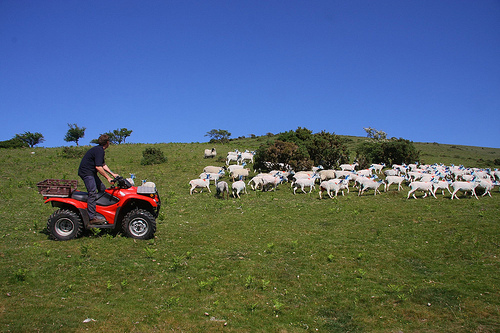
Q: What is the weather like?
A: It is clear.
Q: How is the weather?
A: It is clear.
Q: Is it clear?
A: Yes, it is clear.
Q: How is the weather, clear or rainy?
A: It is clear.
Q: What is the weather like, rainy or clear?
A: It is clear.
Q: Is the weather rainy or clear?
A: It is clear.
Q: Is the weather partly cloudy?
A: No, it is clear.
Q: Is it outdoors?
A: Yes, it is outdoors.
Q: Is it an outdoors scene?
A: Yes, it is outdoors.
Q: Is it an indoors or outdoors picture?
A: It is outdoors.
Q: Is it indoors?
A: No, it is outdoors.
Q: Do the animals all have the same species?
A: Yes, all the animals are sheep.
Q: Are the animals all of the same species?
A: Yes, all the animals are sheep.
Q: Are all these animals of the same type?
A: Yes, all the animals are sheep.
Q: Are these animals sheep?
A: Yes, all the animals are sheep.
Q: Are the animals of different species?
A: No, all the animals are sheep.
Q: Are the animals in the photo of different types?
A: No, all the animals are sheep.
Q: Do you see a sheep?
A: Yes, there is a sheep.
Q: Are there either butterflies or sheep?
A: Yes, there is a sheep.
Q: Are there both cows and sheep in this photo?
A: No, there is a sheep but no cows.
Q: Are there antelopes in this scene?
A: No, there are no antelopes.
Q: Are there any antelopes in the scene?
A: No, there are no antelopes.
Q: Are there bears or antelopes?
A: No, there are no antelopes or bears.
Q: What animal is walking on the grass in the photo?
A: The sheep is walking on the grass.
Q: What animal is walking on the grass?
A: The sheep is walking on the grass.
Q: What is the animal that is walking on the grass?
A: The animal is a sheep.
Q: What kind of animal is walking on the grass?
A: The animal is a sheep.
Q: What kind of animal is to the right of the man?
A: The animal is a sheep.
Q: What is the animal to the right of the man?
A: The animal is a sheep.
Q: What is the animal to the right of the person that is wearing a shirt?
A: The animal is a sheep.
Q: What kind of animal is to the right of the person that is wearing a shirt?
A: The animal is a sheep.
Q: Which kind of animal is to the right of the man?
A: The animal is a sheep.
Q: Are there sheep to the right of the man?
A: Yes, there is a sheep to the right of the man.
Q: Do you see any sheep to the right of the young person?
A: Yes, there is a sheep to the right of the man.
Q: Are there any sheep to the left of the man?
A: No, the sheep is to the right of the man.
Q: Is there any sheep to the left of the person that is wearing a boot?
A: No, the sheep is to the right of the man.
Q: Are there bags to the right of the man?
A: No, there is a sheep to the right of the man.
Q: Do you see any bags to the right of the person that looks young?
A: No, there is a sheep to the right of the man.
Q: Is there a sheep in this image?
A: Yes, there is a sheep.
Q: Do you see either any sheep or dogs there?
A: Yes, there is a sheep.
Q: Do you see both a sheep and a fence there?
A: No, there is a sheep but no fences.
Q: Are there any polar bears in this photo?
A: No, there are no polar bears.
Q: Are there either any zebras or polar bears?
A: No, there are no polar bears or zebras.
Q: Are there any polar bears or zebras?
A: No, there are no polar bears or zebras.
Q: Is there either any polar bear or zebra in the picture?
A: No, there are no polar bears or zebras.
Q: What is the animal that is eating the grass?
A: The animal is a sheep.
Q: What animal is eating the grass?
A: The animal is a sheep.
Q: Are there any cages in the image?
A: No, there are no cages.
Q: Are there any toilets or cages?
A: No, there are no cages or toilets.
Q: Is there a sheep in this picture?
A: Yes, there is a sheep.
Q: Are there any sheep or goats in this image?
A: Yes, there is a sheep.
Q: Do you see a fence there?
A: No, there are no fences.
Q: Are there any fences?
A: No, there are no fences.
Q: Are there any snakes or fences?
A: No, there are no fences or snakes.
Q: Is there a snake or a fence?
A: No, there are no fences or snakes.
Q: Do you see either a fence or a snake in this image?
A: No, there are no fences or snakes.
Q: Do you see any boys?
A: No, there are no boys.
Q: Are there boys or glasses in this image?
A: No, there are no boys or glasses.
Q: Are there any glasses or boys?
A: No, there are no boys or glasses.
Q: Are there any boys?
A: No, there are no boys.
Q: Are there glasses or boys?
A: No, there are no boys or glasses.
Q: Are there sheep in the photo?
A: Yes, there is a sheep.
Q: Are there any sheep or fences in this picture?
A: Yes, there is a sheep.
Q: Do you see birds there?
A: No, there are no birds.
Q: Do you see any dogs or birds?
A: No, there are no birds or dogs.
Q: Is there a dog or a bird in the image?
A: No, there are no birds or dogs.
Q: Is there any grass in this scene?
A: Yes, there is grass.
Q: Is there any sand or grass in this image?
A: Yes, there is grass.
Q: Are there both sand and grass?
A: No, there is grass but no sand.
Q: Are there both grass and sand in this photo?
A: No, there is grass but no sand.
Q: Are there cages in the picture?
A: No, there are no cages.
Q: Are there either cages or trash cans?
A: No, there are no cages or trash cans.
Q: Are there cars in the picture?
A: No, there are no cars.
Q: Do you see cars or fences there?
A: No, there are no cars or fences.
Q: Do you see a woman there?
A: No, there are no women.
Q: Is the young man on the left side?
A: Yes, the man is on the left of the image.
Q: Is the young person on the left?
A: Yes, the man is on the left of the image.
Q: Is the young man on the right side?
A: No, the man is on the left of the image.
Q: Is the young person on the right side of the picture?
A: No, the man is on the left of the image.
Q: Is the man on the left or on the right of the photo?
A: The man is on the left of the image.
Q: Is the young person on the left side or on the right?
A: The man is on the left of the image.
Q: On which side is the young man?
A: The man is on the left of the image.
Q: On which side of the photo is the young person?
A: The man is on the left of the image.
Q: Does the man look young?
A: Yes, the man is young.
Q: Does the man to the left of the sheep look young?
A: Yes, the man is young.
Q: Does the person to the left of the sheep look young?
A: Yes, the man is young.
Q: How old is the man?
A: The man is young.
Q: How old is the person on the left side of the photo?
A: The man is young.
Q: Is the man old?
A: No, the man is young.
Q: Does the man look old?
A: No, the man is young.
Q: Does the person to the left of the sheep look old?
A: No, the man is young.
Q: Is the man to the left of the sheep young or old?
A: The man is young.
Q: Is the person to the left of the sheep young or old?
A: The man is young.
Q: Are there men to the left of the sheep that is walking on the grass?
A: Yes, there is a man to the left of the sheep.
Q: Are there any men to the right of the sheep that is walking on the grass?
A: No, the man is to the left of the sheep.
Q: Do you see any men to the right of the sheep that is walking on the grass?
A: No, the man is to the left of the sheep.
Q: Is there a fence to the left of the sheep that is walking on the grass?
A: No, there is a man to the left of the sheep.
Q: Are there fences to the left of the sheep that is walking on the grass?
A: No, there is a man to the left of the sheep.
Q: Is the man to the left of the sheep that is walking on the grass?
A: Yes, the man is to the left of the sheep.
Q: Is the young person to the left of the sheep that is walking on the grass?
A: Yes, the man is to the left of the sheep.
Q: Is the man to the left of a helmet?
A: No, the man is to the left of the sheep.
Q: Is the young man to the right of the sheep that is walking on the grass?
A: No, the man is to the left of the sheep.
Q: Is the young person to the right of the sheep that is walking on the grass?
A: No, the man is to the left of the sheep.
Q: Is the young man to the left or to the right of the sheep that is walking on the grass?
A: The man is to the left of the sheep.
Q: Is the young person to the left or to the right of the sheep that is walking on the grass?
A: The man is to the left of the sheep.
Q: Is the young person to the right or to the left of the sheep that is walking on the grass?
A: The man is to the left of the sheep.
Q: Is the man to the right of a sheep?
A: No, the man is to the left of a sheep.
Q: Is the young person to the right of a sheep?
A: No, the man is to the left of a sheep.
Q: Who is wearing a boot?
A: The man is wearing a boot.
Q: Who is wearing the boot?
A: The man is wearing a boot.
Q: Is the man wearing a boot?
A: Yes, the man is wearing a boot.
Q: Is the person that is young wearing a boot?
A: Yes, the man is wearing a boot.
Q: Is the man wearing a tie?
A: No, the man is wearing a boot.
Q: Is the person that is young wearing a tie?
A: No, the man is wearing a boot.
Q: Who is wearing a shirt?
A: The man is wearing a shirt.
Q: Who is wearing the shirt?
A: The man is wearing a shirt.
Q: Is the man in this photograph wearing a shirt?
A: Yes, the man is wearing a shirt.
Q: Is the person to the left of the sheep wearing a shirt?
A: Yes, the man is wearing a shirt.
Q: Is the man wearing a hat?
A: No, the man is wearing a shirt.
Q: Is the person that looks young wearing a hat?
A: No, the man is wearing a shirt.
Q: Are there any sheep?
A: Yes, there is a sheep.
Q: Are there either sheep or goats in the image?
A: Yes, there is a sheep.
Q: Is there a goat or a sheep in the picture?
A: Yes, there is a sheep.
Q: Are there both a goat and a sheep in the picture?
A: No, there is a sheep but no goats.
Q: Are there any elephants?
A: No, there are no elephants.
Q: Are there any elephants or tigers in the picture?
A: No, there are no elephants or tigers.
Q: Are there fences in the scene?
A: No, there are no fences.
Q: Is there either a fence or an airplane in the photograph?
A: No, there are no fences or airplanes.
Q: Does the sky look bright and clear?
A: Yes, the sky is bright and clear.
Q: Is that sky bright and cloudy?
A: No, the sky is bright but clear.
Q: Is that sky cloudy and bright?
A: No, the sky is bright but clear.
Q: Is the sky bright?
A: Yes, the sky is bright.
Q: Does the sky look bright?
A: Yes, the sky is bright.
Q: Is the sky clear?
A: Yes, the sky is clear.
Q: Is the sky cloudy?
A: No, the sky is clear.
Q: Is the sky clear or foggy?
A: The sky is clear.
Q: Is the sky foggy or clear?
A: The sky is clear.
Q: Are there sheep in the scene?
A: Yes, there is a sheep.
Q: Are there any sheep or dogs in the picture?
A: Yes, there is a sheep.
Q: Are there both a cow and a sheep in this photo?
A: No, there is a sheep but no cows.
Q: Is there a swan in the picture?
A: No, there are no swans.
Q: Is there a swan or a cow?
A: No, there are no swans or cows.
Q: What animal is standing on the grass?
A: The animal is a sheep.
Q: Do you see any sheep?
A: Yes, there is a sheep.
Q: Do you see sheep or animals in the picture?
A: Yes, there is a sheep.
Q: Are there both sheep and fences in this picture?
A: No, there is a sheep but no fences.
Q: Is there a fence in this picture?
A: No, there are no fences.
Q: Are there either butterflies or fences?
A: No, there are no fences or butterflies.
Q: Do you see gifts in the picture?
A: No, there are no gifts.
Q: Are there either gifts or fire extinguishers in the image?
A: No, there are no gifts or fire extinguishers.